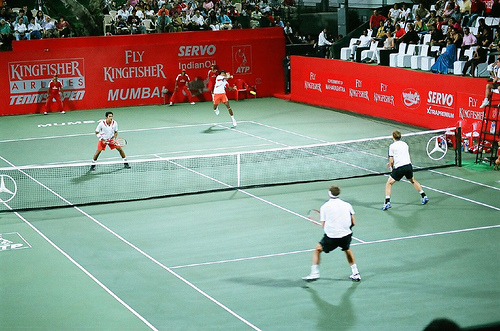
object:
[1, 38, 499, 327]
tennis match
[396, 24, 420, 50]
spectator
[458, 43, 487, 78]
spectator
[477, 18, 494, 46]
spectator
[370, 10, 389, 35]
spectator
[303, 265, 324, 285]
shoe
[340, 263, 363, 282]
shoe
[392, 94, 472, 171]
ground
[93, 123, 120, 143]
shirt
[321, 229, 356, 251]
shorts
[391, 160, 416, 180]
shorts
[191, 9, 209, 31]
person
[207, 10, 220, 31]
person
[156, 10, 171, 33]
person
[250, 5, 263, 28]
person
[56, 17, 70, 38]
person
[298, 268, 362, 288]
shoes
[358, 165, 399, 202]
ground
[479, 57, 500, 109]
umpire chair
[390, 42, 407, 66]
chair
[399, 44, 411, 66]
chair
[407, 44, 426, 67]
chair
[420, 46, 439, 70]
chair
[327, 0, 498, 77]
stands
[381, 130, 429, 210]
man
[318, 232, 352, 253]
black shorts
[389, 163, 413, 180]
black shorts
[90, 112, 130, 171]
man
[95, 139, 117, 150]
red shorts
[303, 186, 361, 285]
man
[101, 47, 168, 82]
advertisement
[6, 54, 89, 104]
advertisement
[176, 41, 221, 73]
advertisement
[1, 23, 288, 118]
wall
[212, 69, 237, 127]
man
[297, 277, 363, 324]
shadow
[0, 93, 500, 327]
court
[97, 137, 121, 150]
shorts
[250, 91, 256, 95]
ball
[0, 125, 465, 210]
net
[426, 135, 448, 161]
logo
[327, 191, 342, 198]
headband